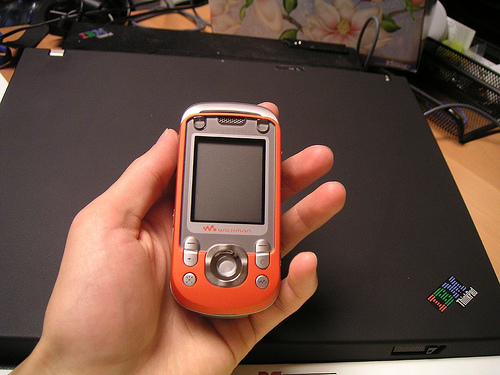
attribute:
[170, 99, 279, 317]
phone — off, orange, silver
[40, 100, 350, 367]
hand — white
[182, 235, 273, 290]
buttons — grey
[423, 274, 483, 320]
logo — colorful, ibm, blue, green, red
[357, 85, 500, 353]
laptop — black, ibm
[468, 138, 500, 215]
table — tan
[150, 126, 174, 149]
nails — short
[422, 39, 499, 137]
holder — metal, black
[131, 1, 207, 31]
wires — black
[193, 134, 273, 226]
screen — grey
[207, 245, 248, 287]
button — silver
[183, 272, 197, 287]
button — silver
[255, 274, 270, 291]
button — silver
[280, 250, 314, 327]
pinky — white, bent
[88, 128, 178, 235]
thumb — white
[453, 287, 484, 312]
letters — white